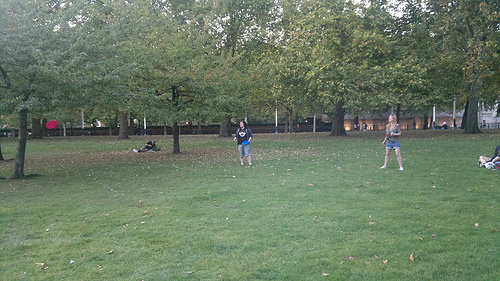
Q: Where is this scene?
A: A park.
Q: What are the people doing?
A: Playing frisbee.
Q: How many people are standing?
A: Two.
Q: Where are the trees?
A: Behind the women.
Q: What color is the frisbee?
A: Red.